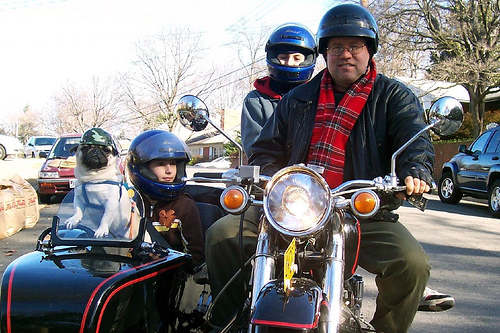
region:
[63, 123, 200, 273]
dog with helmet riding in motorcycle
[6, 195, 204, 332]
black and red motorcycle sidecar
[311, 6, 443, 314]
man riding on a black motorcycle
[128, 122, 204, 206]
child wearing blue motorcycle helmet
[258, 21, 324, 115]
child wearing blue motorcycle helmet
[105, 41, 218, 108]
tree with no leaves in the winter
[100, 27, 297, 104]
power lines in the air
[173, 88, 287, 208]
side mirror on a motorcycle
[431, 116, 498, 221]
black SUV parked on the street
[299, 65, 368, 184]
red plaid scarf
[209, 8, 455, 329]
motorcyclist with passenger on back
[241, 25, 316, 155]
boy on back of motorcycle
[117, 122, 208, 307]
passenger in sidecar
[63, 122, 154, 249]
dog riding in sidecar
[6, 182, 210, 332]
sidecar attached to motorcycle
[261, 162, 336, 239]
headlight on motorcycle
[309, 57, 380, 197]
red plaid scarf on driver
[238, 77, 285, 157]
hoodie on boy behind driver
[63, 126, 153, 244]
dog wearing a harness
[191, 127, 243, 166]
house behind motorcycle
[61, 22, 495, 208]
Family riding the motorcycle.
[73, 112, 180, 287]
Dog in the motorcycle.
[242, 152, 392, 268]
Motorcycle headlight.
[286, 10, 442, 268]
Man wearing a scarf.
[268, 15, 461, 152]
Man on a motorcycle.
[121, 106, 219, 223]
A child in the side cart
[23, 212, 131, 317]
Black side cart with red stripes.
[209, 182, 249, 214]
Motorcycle turn signals.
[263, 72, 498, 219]
Man with black jacket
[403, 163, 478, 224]
Man with leather gloves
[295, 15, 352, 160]
the man is wearing scarf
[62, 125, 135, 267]
the dog is wearing a helmet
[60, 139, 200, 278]
the dog is riding the side car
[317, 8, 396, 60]
the helmet is black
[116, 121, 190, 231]
the kid is wearing helmet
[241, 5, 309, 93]
the helmet is blue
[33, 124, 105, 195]
the car is red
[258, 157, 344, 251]
the headlight is on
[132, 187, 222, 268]
the jacket is brown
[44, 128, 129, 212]
the car is parked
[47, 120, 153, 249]
a chubby pug dog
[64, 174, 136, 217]
a blue dog halter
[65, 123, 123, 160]
a camo dog helmet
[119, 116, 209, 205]
a blue motorcycle helmet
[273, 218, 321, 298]
a bright yellow license plate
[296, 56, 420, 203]
a red plaid scarf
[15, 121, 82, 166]
a small white suv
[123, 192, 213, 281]
a children's brown jacket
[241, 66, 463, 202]
a black leather jacket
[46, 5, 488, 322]
a family motorcycle ride